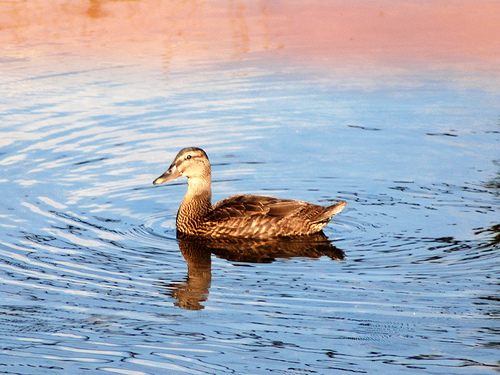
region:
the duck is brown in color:
[82, 121, 448, 312]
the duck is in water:
[71, 131, 419, 373]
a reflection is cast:
[48, 148, 285, 348]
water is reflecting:
[103, 146, 314, 372]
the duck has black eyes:
[90, 119, 388, 306]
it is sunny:
[17, 14, 455, 343]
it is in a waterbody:
[0, 53, 455, 359]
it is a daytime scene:
[10, 52, 436, 349]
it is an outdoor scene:
[6, 58, 413, 373]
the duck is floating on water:
[102, 102, 413, 316]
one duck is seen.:
[156, 142, 346, 247]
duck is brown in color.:
[141, 141, 373, 257]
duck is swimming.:
[155, 140, 312, 272]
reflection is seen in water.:
[151, 220, 346, 310]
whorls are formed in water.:
[110, 255, 310, 335]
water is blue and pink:
[266, 15, 433, 95]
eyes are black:
[185, 151, 195, 161]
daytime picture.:
[42, 51, 394, 305]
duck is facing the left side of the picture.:
[140, 131, 352, 295]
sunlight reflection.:
[53, 20, 273, 131]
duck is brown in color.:
[166, 191, 336, 246]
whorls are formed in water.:
[122, 272, 392, 362]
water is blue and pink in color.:
[285, 23, 422, 116]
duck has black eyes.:
[184, 152, 199, 161]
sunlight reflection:
[29, 28, 179, 154]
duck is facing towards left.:
[133, 131, 278, 223]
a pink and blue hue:
[0, 1, 496, 367]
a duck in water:
[107, 136, 372, 279]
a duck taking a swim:
[120, 130, 369, 272]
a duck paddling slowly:
[118, 127, 368, 271]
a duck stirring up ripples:
[50, 136, 463, 317]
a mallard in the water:
[102, 115, 368, 281]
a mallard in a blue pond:
[88, 124, 371, 309]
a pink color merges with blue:
[0, 0, 492, 332]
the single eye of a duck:
[85, 99, 420, 298]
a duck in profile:
[86, 106, 383, 275]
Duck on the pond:
[140, 135, 378, 269]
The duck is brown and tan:
[163, 140, 372, 295]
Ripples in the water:
[47, 124, 442, 289]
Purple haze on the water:
[43, 48, 291, 118]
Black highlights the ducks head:
[161, 140, 281, 232]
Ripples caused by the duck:
[149, 143, 461, 310]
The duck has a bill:
[154, 136, 238, 216]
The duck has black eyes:
[175, 141, 207, 177]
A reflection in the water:
[66, 5, 177, 66]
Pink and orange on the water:
[52, 25, 316, 83]